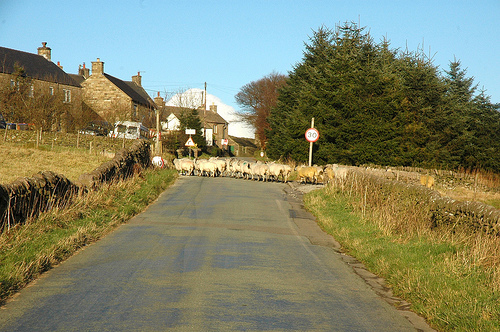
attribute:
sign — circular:
[305, 128, 319, 141]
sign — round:
[304, 126, 318, 142]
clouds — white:
[160, 6, 280, 58]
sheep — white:
[142, 128, 359, 208]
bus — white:
[102, 111, 143, 140]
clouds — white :
[109, 11, 260, 53]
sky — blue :
[0, 2, 499, 100]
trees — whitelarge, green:
[269, 27, 498, 179]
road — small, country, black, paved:
[9, 172, 426, 329]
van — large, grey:
[108, 114, 148, 141]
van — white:
[104, 112, 150, 141]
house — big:
[78, 64, 153, 139]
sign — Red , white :
[303, 117, 322, 152]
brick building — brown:
[80, 56, 161, 138]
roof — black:
[101, 72, 146, 105]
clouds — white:
[171, 84, 268, 148]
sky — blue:
[5, 5, 497, 124]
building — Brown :
[24, 25, 251, 193]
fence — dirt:
[1, 162, 136, 262]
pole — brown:
[297, 105, 338, 181]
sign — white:
[298, 115, 328, 147]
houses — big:
[0, 35, 237, 158]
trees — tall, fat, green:
[261, 18, 498, 173]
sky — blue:
[0, 0, 500, 135]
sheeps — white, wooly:
[175, 149, 295, 183]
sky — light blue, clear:
[0, 0, 499, 111]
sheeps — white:
[159, 144, 356, 202]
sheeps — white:
[282, 163, 293, 183]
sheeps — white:
[268, 161, 287, 181]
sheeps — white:
[260, 161, 274, 182]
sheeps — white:
[194, 158, 216, 178]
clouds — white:
[157, 61, 263, 113]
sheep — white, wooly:
[193, 153, 226, 176]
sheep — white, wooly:
[260, 161, 291, 182]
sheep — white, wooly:
[230, 159, 249, 175]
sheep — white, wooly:
[201, 153, 227, 182]